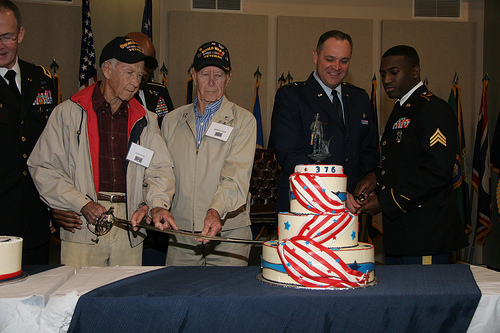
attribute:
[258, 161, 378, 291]
cake — red, heap, layered, three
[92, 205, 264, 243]
sword — cutting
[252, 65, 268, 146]
pole — tip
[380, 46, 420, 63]
hair — black, short, brown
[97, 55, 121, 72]
hair — grey